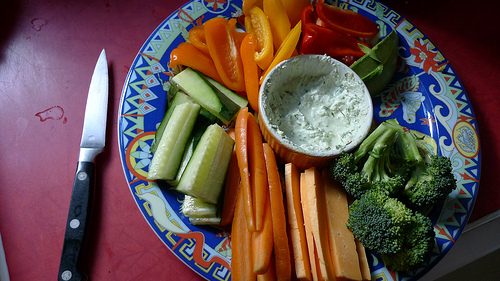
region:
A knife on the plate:
[56, 49, 107, 279]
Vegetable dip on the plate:
[259, 54, 372, 164]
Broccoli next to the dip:
[333, 119, 458, 269]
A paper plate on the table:
[118, 0, 478, 280]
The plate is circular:
[118, 1, 480, 280]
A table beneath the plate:
[0, 0, 497, 279]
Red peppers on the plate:
[303, 2, 379, 55]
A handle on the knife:
[60, 162, 92, 279]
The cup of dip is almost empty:
[259, 54, 371, 166]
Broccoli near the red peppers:
[339, 118, 454, 273]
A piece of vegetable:
[181, 126, 258, 214]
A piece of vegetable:
[234, 151, 302, 256]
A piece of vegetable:
[314, 179, 381, 274]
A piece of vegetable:
[184, 2, 268, 86]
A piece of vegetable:
[167, 39, 211, 89]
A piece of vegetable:
[397, 133, 461, 228]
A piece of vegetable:
[361, 182, 439, 263]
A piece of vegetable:
[345, 69, 419, 196]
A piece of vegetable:
[242, 18, 314, 49]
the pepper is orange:
[200, 38, 231, 59]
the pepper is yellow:
[264, 16, 281, 43]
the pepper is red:
[321, 24, 338, 46]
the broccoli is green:
[361, 171, 402, 197]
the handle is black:
[65, 191, 92, 220]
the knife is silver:
[81, 83, 111, 124]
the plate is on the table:
[126, 26, 168, 51]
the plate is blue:
[147, 112, 157, 128]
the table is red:
[15, 44, 51, 79]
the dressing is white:
[295, 88, 343, 135]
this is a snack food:
[25, 38, 382, 253]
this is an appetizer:
[49, 76, 330, 219]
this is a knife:
[62, 64, 119, 276]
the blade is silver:
[70, 70, 130, 165]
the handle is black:
[47, 165, 117, 279]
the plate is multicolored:
[120, 62, 185, 148]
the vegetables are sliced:
[127, 34, 406, 255]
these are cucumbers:
[155, 69, 224, 184]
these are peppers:
[186, 30, 276, 72]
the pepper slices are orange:
[185, 25, 281, 106]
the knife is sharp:
[58, 47, 108, 279]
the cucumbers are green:
[151, 64, 248, 225]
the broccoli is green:
[335, 115, 457, 276]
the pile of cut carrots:
[223, 106, 290, 279]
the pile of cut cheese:
[283, 161, 370, 279]